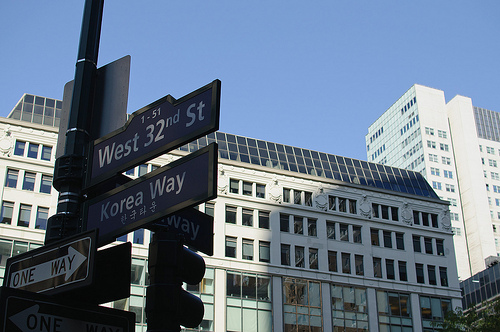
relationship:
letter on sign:
[107, 200, 121, 219] [42, 131, 239, 265]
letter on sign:
[162, 176, 179, 195] [76, 90, 208, 271]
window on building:
[428, 209, 440, 226] [0, 90, 465, 329]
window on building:
[438, 263, 452, 287] [0, 90, 465, 329]